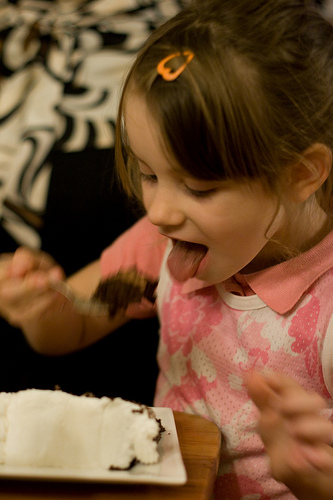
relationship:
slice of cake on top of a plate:
[4, 398, 149, 473] [0, 404, 186, 486]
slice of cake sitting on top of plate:
[4, 398, 149, 473] [0, 404, 186, 486]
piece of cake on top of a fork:
[100, 266, 161, 317] [2, 196, 116, 328]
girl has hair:
[17, 7, 326, 457] [143, 3, 333, 150]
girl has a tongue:
[17, 7, 326, 457] [163, 239, 210, 284]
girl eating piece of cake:
[17, 7, 326, 457] [100, 266, 161, 317]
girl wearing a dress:
[17, 7, 326, 457] [91, 221, 332, 487]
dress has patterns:
[91, 221, 332, 487] [173, 318, 236, 405]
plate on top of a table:
[0, 404, 186, 486] [1, 390, 222, 500]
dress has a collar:
[91, 221, 332, 487] [239, 258, 331, 317]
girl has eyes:
[17, 7, 326, 457] [123, 157, 238, 208]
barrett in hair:
[150, 46, 193, 88] [143, 3, 333, 150]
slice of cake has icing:
[4, 398, 149, 473] [26, 415, 81, 453]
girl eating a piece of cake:
[17, 7, 326, 457] [100, 266, 161, 317]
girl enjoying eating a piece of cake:
[17, 7, 326, 457] [100, 266, 161, 317]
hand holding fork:
[0, 248, 74, 330] [2, 196, 116, 328]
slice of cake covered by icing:
[4, 398, 149, 473] [26, 415, 81, 453]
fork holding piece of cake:
[2, 196, 116, 328] [100, 266, 161, 317]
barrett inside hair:
[150, 46, 193, 88] [143, 3, 333, 150]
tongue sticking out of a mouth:
[163, 239, 210, 284] [148, 225, 232, 287]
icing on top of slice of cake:
[26, 415, 81, 453] [4, 398, 149, 473]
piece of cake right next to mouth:
[100, 266, 161, 317] [148, 225, 232, 287]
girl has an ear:
[17, 7, 326, 457] [282, 131, 333, 209]